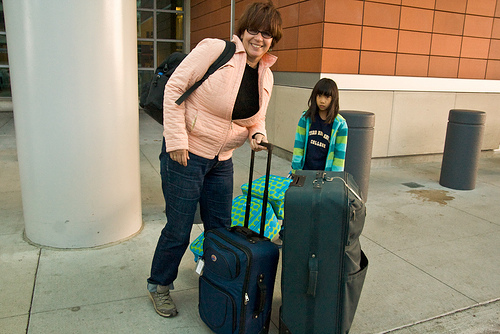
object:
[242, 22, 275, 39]
glasses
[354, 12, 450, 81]
orange bricks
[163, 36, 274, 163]
jacket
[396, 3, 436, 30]
tile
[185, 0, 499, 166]
wall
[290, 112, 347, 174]
jacket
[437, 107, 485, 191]
trashcan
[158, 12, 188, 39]
window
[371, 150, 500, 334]
part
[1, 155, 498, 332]
sidewalk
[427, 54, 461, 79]
tile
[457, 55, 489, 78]
tile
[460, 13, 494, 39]
tile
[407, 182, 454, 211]
stain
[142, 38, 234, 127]
backpack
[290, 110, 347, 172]
sweater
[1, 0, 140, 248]
white column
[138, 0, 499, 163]
building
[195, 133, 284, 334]
carry on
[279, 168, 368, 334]
carry on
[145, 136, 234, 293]
jeans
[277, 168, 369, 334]
upright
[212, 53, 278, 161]
zip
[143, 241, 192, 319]
up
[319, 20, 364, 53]
block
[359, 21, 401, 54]
block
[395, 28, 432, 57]
block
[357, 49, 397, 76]
block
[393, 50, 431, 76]
block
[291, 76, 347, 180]
daughter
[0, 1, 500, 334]
airport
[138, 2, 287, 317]
mom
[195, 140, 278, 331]
luggage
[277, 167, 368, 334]
luggage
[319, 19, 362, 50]
brick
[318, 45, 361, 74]
brick